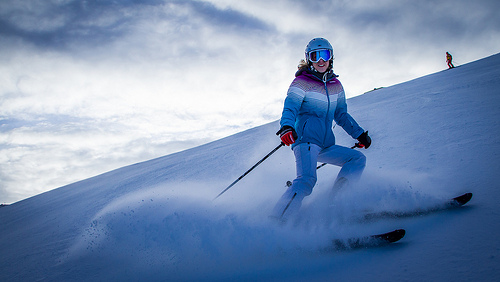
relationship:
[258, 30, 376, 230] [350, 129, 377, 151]
woman wearing glove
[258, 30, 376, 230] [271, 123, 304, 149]
woman wearing glove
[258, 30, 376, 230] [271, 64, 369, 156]
woman wearing jacket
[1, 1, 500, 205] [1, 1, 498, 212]
clouds in sky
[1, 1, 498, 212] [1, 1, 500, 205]
sky has clouds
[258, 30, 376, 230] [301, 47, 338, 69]
woman wearing goggles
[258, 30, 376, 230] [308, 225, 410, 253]
woman has ski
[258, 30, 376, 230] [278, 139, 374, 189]
woman wearing pants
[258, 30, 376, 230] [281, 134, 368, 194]
woman has ski pole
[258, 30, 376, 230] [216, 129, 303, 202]
woman has ski pole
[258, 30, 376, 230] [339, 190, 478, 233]
woman has ski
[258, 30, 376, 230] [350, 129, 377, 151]
woman has glove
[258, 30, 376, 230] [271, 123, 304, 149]
woman has glove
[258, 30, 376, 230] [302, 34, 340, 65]
woman wearing helmet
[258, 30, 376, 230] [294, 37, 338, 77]
woman has head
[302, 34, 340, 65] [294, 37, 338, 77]
helmet on head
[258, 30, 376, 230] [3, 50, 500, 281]
woman on mountain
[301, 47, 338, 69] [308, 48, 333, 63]
goggles have goggles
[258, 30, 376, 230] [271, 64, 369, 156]
woman has jacket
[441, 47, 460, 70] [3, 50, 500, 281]
skier on mountain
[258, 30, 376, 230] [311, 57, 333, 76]
woman has face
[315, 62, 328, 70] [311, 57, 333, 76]
smile on face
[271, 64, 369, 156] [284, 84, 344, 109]
jacket has stripe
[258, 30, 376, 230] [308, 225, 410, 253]
woman on ski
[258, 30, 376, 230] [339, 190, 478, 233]
woman on ski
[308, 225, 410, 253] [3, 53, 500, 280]
ski on snow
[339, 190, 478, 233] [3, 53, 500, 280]
ski on snow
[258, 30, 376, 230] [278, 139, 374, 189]
woman has pants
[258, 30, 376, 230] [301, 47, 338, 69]
woman has goggles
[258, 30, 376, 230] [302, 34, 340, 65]
woman has helmet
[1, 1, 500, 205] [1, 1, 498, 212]
clouds are in sky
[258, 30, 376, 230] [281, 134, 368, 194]
woman holding ski pole